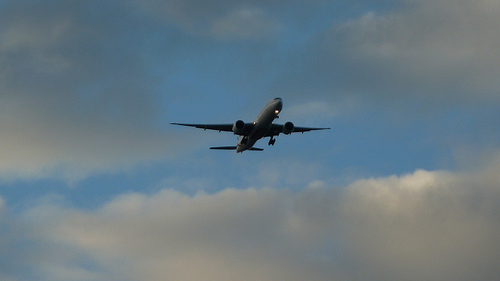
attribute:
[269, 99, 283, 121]
tip —  plane 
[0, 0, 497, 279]
sky — part 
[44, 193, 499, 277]
cloud — edge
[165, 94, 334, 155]
plane — tip 